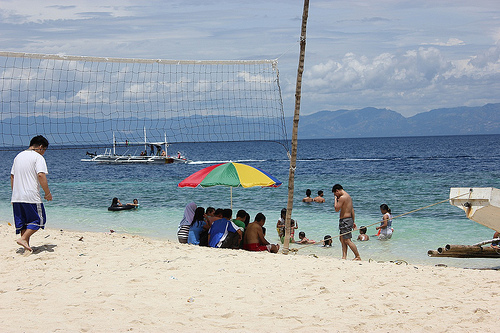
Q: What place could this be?
A: It is a beach.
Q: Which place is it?
A: It is a beach.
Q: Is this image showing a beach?
A: Yes, it is showing a beach.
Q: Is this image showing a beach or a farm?
A: It is showing a beach.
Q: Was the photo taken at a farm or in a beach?
A: It was taken at a beach.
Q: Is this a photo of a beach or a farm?
A: It is showing a beach.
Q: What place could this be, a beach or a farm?
A: It is a beach.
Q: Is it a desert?
A: No, it is a beach.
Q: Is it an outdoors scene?
A: Yes, it is outdoors.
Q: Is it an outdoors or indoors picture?
A: It is outdoors.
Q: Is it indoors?
A: No, it is outdoors.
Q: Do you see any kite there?
A: No, there are no kites.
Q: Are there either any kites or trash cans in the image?
A: No, there are no kites or trash cans.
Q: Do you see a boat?
A: Yes, there is a boat.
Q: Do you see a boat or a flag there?
A: Yes, there is a boat.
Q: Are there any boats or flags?
A: Yes, there is a boat.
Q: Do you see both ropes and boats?
A: Yes, there are both a boat and a rope.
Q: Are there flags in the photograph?
A: No, there are no flags.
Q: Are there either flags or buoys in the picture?
A: No, there are no flags or buoys.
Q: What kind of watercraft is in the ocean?
A: The watercraft is a boat.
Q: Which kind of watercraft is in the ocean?
A: The watercraft is a boat.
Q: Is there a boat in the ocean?
A: Yes, there is a boat in the ocean.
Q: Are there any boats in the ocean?
A: Yes, there is a boat in the ocean.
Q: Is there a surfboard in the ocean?
A: No, there is a boat in the ocean.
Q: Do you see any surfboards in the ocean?
A: No, there is a boat in the ocean.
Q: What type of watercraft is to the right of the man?
A: The watercraft is a boat.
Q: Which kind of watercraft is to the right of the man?
A: The watercraft is a boat.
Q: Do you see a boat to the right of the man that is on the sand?
A: Yes, there is a boat to the right of the man.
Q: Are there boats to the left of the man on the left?
A: No, the boat is to the right of the man.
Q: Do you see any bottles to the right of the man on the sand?
A: No, there is a boat to the right of the man.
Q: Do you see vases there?
A: No, there are no vases.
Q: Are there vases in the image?
A: No, there are no vases.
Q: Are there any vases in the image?
A: No, there are no vases.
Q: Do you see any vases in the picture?
A: No, there are no vases.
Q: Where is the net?
A: The net is on the beach.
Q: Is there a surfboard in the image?
A: No, there are no surfboards.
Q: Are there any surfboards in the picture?
A: No, there are no surfboards.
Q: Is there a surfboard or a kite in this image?
A: No, there are no surfboards or kites.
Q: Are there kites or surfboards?
A: No, there are no surfboards or kites.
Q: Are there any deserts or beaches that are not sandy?
A: No, there is a beach but it is sandy.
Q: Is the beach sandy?
A: Yes, the beach is sandy.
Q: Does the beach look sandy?
A: Yes, the beach is sandy.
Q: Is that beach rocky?
A: No, the beach is sandy.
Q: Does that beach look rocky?
A: No, the beach is sandy.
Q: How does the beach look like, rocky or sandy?
A: The beach is sandy.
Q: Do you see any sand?
A: Yes, there is sand.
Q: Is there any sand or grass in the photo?
A: Yes, there is sand.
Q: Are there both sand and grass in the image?
A: No, there is sand but no grass.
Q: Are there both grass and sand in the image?
A: No, there is sand but no grass.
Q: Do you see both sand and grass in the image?
A: No, there is sand but no grass.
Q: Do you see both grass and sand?
A: No, there is sand but no grass.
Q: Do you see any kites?
A: No, there are no kites.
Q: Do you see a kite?
A: No, there are no kites.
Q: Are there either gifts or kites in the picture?
A: No, there are no kites or gifts.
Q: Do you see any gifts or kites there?
A: No, there are no kites or gifts.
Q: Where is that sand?
A: The sand is on the beach.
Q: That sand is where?
A: The sand is on the beach.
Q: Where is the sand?
A: The sand is on the beach.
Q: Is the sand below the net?
A: Yes, the sand is below the net.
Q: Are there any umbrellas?
A: Yes, there is an umbrella.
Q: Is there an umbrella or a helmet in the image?
A: Yes, there is an umbrella.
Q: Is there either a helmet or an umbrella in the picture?
A: Yes, there is an umbrella.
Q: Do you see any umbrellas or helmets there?
A: Yes, there is an umbrella.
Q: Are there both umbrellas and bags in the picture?
A: No, there is an umbrella but no bags.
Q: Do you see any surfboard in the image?
A: No, there are no surfboards.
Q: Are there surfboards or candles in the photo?
A: No, there are no surfboards or candles.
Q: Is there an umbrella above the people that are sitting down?
A: Yes, there is an umbrella above the people.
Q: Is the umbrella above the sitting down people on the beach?
A: Yes, the umbrella is above the people.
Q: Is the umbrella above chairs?
A: No, the umbrella is above the people.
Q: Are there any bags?
A: No, there are no bags.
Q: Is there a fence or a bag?
A: No, there are no bags or fences.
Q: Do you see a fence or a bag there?
A: No, there are no bags or fences.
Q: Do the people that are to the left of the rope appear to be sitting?
A: Yes, the people are sitting.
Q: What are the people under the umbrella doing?
A: The people are sitting.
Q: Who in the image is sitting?
A: The people are sitting.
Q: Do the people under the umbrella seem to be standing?
A: No, the people are sitting.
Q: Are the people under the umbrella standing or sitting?
A: The people are sitting.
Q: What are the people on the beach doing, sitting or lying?
A: The people are sitting.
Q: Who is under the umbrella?
A: The people are under the umbrella.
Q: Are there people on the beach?
A: Yes, there are people on the beach.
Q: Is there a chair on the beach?
A: No, there are people on the beach.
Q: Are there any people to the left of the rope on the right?
A: Yes, there are people to the left of the rope.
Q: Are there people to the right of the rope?
A: No, the people are to the left of the rope.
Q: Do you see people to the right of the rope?
A: No, the people are to the left of the rope.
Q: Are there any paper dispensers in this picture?
A: No, there are no paper dispensers.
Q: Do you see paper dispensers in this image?
A: No, there are no paper dispensers.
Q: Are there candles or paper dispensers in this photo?
A: No, there are no paper dispensers or candles.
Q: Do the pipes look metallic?
A: Yes, the pipes are metallic.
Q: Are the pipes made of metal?
A: Yes, the pipes are made of metal.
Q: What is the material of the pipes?
A: The pipes are made of metal.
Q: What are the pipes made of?
A: The pipes are made of metal.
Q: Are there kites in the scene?
A: No, there are no kites.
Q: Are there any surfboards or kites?
A: No, there are no kites or surfboards.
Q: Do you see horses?
A: No, there are no horses.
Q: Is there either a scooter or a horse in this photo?
A: No, there are no horses or scooters.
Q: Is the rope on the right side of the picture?
A: Yes, the rope is on the right of the image.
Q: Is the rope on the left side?
A: No, the rope is on the right of the image.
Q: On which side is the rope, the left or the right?
A: The rope is on the right of the image.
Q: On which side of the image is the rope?
A: The rope is on the right of the image.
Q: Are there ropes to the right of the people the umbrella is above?
A: Yes, there is a rope to the right of the people.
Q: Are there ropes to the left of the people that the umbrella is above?
A: No, the rope is to the right of the people.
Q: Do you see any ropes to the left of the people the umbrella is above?
A: No, the rope is to the right of the people.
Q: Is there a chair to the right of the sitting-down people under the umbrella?
A: No, there is a rope to the right of the people.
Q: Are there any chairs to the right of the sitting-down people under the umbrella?
A: No, there is a rope to the right of the people.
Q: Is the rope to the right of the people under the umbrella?
A: Yes, the rope is to the right of the people.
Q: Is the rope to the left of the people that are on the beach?
A: No, the rope is to the right of the people.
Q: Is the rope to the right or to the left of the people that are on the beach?
A: The rope is to the right of the people.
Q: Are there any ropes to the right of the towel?
A: Yes, there is a rope to the right of the towel.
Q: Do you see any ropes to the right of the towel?
A: Yes, there is a rope to the right of the towel.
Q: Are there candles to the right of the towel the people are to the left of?
A: No, there is a rope to the right of the towel.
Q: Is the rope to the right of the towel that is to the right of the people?
A: Yes, the rope is to the right of the towel.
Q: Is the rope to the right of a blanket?
A: No, the rope is to the right of the towel.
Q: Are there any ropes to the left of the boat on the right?
A: Yes, there is a rope to the left of the boat.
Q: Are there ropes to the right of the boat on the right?
A: No, the rope is to the left of the boat.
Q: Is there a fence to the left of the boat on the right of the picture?
A: No, there is a rope to the left of the boat.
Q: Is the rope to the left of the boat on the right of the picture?
A: Yes, the rope is to the left of the boat.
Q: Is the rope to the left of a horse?
A: No, the rope is to the left of the boat.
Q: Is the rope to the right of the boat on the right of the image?
A: No, the rope is to the left of the boat.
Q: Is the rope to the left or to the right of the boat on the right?
A: The rope is to the left of the boat.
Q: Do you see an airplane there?
A: No, there are no airplanes.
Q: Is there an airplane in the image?
A: No, there are no airplanes.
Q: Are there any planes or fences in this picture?
A: No, there are no planes or fences.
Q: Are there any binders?
A: No, there are no binders.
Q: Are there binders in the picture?
A: No, there are no binders.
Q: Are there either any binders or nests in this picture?
A: No, there are no binders or nests.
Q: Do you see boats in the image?
A: Yes, there is a boat.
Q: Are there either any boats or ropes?
A: Yes, there is a boat.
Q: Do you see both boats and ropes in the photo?
A: Yes, there are both a boat and a rope.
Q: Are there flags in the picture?
A: No, there are no flags.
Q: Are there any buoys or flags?
A: No, there are no flags or buoys.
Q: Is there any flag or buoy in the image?
A: No, there are no flags or buoys.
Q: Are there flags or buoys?
A: No, there are no flags or buoys.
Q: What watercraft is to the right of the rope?
A: The watercraft is a boat.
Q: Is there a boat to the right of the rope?
A: Yes, there is a boat to the right of the rope.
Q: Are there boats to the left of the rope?
A: No, the boat is to the right of the rope.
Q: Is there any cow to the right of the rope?
A: No, there is a boat to the right of the rope.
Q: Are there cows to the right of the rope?
A: No, there is a boat to the right of the rope.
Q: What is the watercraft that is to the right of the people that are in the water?
A: The watercraft is a boat.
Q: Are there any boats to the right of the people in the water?
A: Yes, there is a boat to the right of the people.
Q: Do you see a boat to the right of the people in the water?
A: Yes, there is a boat to the right of the people.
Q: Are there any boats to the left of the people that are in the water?
A: No, the boat is to the right of the people.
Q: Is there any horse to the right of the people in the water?
A: No, there is a boat to the right of the people.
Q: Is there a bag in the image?
A: No, there are no bags.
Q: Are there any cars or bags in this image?
A: No, there are no bags or cars.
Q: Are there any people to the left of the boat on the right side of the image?
A: Yes, there are people to the left of the boat.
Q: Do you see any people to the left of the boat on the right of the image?
A: Yes, there are people to the left of the boat.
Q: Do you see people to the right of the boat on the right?
A: No, the people are to the left of the boat.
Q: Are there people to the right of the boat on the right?
A: No, the people are to the left of the boat.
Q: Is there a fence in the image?
A: No, there are no fences.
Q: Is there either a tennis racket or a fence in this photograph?
A: No, there are no fences or rackets.